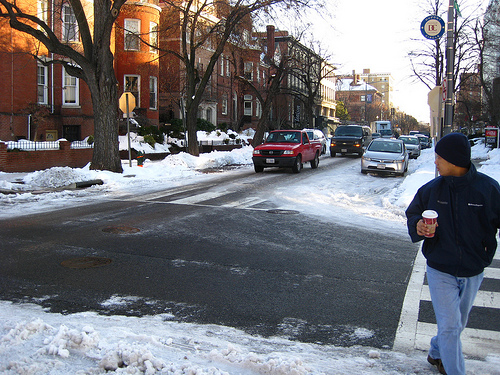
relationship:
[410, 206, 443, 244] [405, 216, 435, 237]
cup in hand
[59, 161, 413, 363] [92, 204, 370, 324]
crosswalk on street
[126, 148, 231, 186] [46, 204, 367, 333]
piles by street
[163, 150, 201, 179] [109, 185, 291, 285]
snow piled on street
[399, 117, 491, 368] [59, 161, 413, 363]
man crosses street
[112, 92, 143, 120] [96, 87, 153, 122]
back of sign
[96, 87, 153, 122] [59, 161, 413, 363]
sign by street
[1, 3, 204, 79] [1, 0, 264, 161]
sunlight on buildings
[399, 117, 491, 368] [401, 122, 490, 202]
man looking back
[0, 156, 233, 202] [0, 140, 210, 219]
snow on sidewalks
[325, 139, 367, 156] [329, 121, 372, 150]
lights on van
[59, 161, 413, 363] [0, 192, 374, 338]
snow on road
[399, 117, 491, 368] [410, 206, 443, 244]
man holds cup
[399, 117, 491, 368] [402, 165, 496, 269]
man wearing jacket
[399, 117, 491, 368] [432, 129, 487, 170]
man wears hat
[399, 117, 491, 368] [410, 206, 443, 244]
man carry coffee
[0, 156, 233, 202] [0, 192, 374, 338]
snow on road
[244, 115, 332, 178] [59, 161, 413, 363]
truck on street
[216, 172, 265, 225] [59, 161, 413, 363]
markings on street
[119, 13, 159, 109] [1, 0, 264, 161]
windows on buildings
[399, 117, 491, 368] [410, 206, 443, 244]
man holding cup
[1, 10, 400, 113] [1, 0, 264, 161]
row of buildings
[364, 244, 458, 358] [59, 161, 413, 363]
crosswalk on street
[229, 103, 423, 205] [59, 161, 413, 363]
cars on street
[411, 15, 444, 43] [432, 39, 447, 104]
sign on pole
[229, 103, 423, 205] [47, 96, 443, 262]
cars at intersection